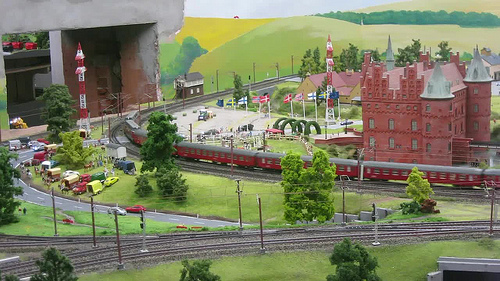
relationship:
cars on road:
[87, 196, 184, 234] [52, 191, 224, 248]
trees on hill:
[135, 124, 187, 184] [112, 180, 197, 206]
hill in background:
[112, 180, 197, 206] [277, 3, 499, 57]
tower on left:
[60, 45, 105, 120] [4, 17, 172, 205]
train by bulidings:
[185, 141, 281, 171] [318, 30, 487, 178]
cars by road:
[87, 196, 184, 234] [52, 191, 224, 248]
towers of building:
[373, 37, 490, 101] [359, 42, 494, 175]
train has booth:
[185, 141, 281, 171] [173, 63, 231, 112]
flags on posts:
[229, 79, 355, 116] [242, 99, 343, 125]